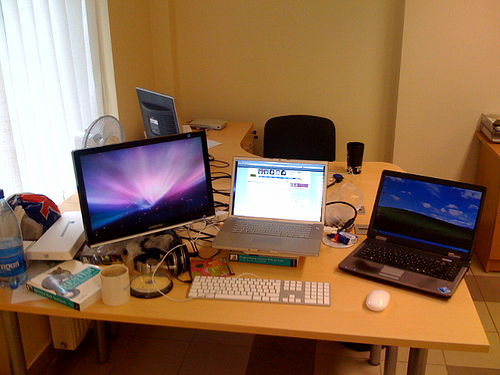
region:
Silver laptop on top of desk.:
[232, 160, 313, 262]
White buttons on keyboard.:
[189, 268, 361, 318]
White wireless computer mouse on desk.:
[358, 276, 402, 338]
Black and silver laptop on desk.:
[369, 180, 447, 327]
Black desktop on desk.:
[66, 181, 215, 227]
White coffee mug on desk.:
[88, 248, 135, 302]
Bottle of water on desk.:
[1, 195, 31, 311]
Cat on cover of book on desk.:
[31, 255, 118, 323]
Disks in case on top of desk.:
[134, 264, 170, 311]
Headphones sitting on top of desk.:
[143, 236, 208, 276]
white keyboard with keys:
[195, 277, 335, 307]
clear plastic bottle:
[0, 190, 32, 296]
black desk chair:
[256, 106, 336, 161]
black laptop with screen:
[333, 155, 490, 307]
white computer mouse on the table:
[359, 285, 389, 315]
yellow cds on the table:
[135, 269, 170, 303]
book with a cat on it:
[31, 262, 106, 312]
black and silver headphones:
[137, 246, 191, 279]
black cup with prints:
[338, 138, 370, 177]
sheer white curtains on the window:
[5, 79, 64, 169]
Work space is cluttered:
[4, 83, 489, 353]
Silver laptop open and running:
[210, 155, 330, 257]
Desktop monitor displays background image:
[69, 128, 216, 248]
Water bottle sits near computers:
[0, 185, 29, 290]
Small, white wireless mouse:
[365, 287, 392, 312]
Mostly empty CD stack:
[129, 255, 174, 300]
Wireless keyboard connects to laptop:
[185, 273, 332, 308]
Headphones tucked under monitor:
[131, 230, 192, 275]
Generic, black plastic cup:
[344, 139, 365, 176]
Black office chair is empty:
[258, 115, 338, 162]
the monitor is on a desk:
[70, 126, 215, 247]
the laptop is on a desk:
[209, 153, 324, 265]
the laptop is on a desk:
[337, 168, 484, 304]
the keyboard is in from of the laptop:
[184, 270, 333, 307]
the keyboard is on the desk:
[188, 273, 330, 310]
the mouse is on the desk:
[364, 284, 392, 311]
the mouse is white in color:
[361, 286, 394, 311]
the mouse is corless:
[362, 287, 390, 313]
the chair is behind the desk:
[262, 114, 337, 163]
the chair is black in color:
[258, 111, 340, 163]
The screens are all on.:
[61, 108, 496, 259]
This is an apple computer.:
[226, 148, 328, 283]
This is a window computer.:
[359, 160, 471, 305]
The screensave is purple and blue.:
[85, 151, 197, 217]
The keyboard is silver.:
[185, 258, 346, 330]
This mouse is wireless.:
[353, 291, 403, 324]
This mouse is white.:
[341, 273, 424, 339]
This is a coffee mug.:
[81, 270, 138, 313]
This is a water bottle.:
[4, 186, 34, 299]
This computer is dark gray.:
[338, 231, 465, 286]